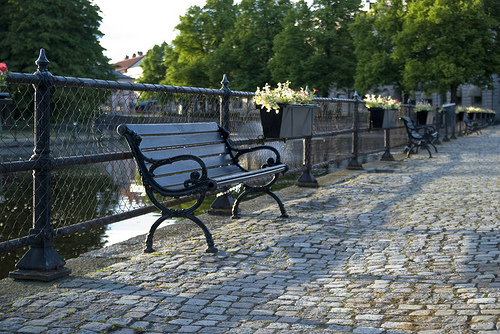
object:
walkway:
[0, 117, 498, 329]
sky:
[113, 11, 155, 33]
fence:
[3, 48, 499, 258]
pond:
[1, 125, 423, 277]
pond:
[0, 121, 465, 281]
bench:
[110, 117, 292, 264]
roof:
[111, 52, 146, 72]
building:
[111, 50, 149, 94]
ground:
[268, 238, 348, 302]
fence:
[57, 87, 106, 208]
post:
[26, 43, 75, 298]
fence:
[156, 83, 387, 133]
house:
[97, 49, 182, 110]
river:
[9, 118, 484, 275]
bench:
[97, 100, 337, 279]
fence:
[48, 66, 127, 153]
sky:
[87, 4, 197, 64]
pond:
[2, 98, 397, 248]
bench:
[117, 118, 289, 250]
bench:
[401, 114, 437, 156]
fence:
[3, 52, 493, 275]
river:
[2, 159, 157, 274]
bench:
[119, 114, 311, 254]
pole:
[14, 43, 65, 273]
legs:
[141, 172, 290, 257]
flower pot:
[260, 101, 317, 141]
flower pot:
[368, 108, 403, 130]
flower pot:
[412, 107, 436, 124]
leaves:
[264, 17, 359, 93]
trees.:
[181, 9, 444, 99]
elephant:
[249, 77, 320, 119]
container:
[260, 103, 312, 137]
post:
[17, 52, 73, 289]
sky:
[92, 0, 209, 62]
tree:
[1, 1, 115, 126]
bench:
[131, 120, 265, 235]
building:
[113, 34, 142, 75]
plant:
[251, 76, 323, 116]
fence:
[0, 64, 460, 284]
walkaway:
[6, 125, 496, 332]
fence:
[0, 51, 471, 290]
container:
[259, 92, 324, 140]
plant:
[250, 81, 323, 118]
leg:
[138, 211, 223, 252]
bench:
[115, 113, 299, 260]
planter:
[259, 99, 321, 137]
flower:
[254, 75, 319, 112]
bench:
[126, 116, 289, 263]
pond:
[50, 162, 140, 230]